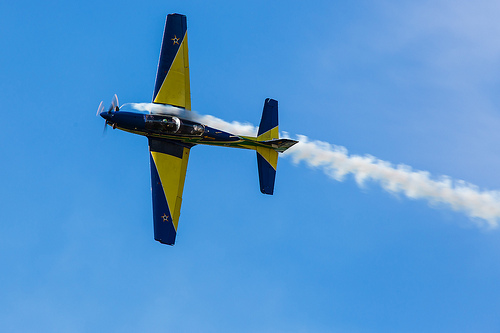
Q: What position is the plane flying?
A: Sideways.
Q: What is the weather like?
A: Clear skies.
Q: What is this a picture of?
A: An airplane.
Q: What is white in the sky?
A: Exhaust.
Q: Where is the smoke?
A: Behind the plane.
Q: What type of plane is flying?
A: Stunt plane.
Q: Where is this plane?
A: Sky.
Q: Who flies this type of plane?
A: Pilot.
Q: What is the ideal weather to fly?
A: Sunny.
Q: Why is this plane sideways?
A: Doing tricks.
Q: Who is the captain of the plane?
A: Pilot.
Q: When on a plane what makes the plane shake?
A: Turbulence.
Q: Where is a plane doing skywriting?
A: In the sky.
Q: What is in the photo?
A: A plane.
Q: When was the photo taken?
A: Daytime.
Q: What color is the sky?
A: Blue.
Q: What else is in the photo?
A: Sky.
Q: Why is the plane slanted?
A: To enable quick movement.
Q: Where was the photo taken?
A: Airplane show.